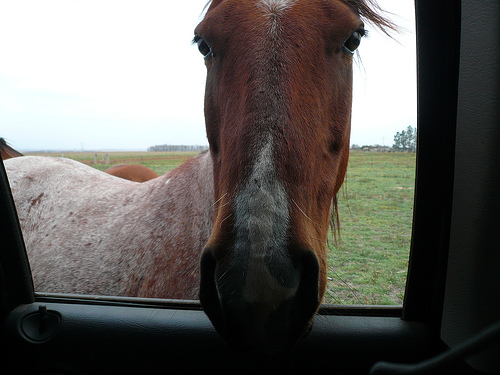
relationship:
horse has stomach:
[13, 0, 371, 335] [42, 223, 184, 292]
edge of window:
[41, 69, 314, 306] [91, 265, 220, 305]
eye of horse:
[190, 28, 240, 70] [13, 0, 371, 335]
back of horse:
[41, 159, 165, 217] [13, 0, 371, 335]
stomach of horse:
[42, 223, 184, 292] [13, 0, 371, 335]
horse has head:
[13, 0, 371, 335] [216, 16, 326, 265]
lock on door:
[28, 297, 67, 341] [27, 280, 320, 349]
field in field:
[349, 152, 402, 301] [81, 139, 220, 174]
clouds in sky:
[14, 30, 222, 152] [34, 23, 155, 111]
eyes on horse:
[183, 18, 384, 51] [54, 27, 378, 279]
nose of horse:
[199, 244, 320, 349] [13, 0, 371, 335]